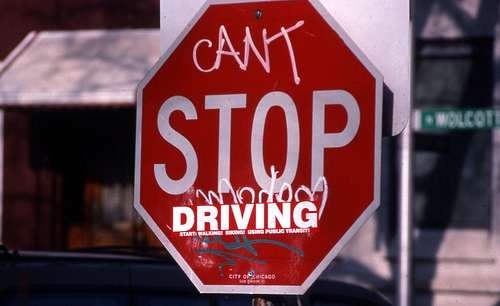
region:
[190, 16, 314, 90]
graffiti on stop sign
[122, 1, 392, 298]
octagon shaped stop sign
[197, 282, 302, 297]
white border on stop sign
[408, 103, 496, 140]
green and white street sign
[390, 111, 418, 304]
metal street sign support pole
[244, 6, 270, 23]
nail in stop sign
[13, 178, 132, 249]
shadows on wall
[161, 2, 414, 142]
white sign behind stop sign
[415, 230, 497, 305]
concrete structure behind stree sign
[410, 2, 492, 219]
shadow of tree on wall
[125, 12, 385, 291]
this is a poster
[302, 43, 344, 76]
the poster is red in color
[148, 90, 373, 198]
it is written stop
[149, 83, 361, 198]
the writing is stop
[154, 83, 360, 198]
it is written is bold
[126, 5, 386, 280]
the shape is hexagonal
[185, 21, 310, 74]
this is written cant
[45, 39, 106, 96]
this is the roof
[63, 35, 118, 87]
the roof is short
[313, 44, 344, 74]
the poster is bright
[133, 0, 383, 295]
vandalized red stop sign with white border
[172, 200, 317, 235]
red and white bumber sticker encourages public transportation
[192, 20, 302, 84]
white graffiti writing misspells a common contraction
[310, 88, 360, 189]
large white capital P in a sans serif font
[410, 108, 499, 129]
blurry green sign indicating wolcott street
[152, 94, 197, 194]
large white capital S in a sans serif font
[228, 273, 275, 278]
text indicates this sign is in Chicago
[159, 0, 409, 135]
the back of another sign sharing pole space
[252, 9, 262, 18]
grey metal bolt holding up the sign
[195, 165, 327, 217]
older graffiti is no longer relevant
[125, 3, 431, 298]
Octagonal stop signal board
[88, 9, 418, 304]
Red color background of the signal board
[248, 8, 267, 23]
Bolt of the signal board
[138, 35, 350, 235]
White color letters in the signal board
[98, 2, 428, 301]
signal board attached in the metal pole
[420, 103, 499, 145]
Green color background with white color letter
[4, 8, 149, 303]
Buildings near the signal board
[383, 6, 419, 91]
White color metal pole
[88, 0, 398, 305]
Octagonal shape white color border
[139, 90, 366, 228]
Big size stop letter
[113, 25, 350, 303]
Red street sign attached to pole.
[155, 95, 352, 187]
Large white letters on sign.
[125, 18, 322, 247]
Red sign has 8 sides.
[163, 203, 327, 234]
Sticker stuck on to sign.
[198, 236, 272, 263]
Gray graffiti on red sign.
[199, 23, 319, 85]
White graffiti on red sign.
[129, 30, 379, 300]
White edging on red sign.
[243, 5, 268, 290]
2 screws on red sign.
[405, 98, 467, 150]
Green street sign attached to pole.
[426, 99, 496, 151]
White lettering on green sing.